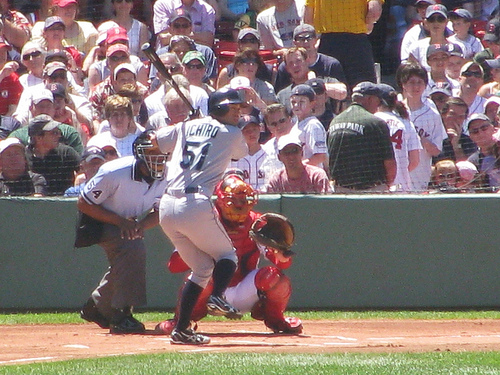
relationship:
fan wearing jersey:
[397, 63, 450, 155] [405, 101, 448, 191]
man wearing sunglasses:
[105, 43, 135, 75] [106, 53, 128, 62]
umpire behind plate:
[72, 125, 172, 337] [153, 329, 173, 345]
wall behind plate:
[2, 193, 500, 318] [153, 329, 173, 345]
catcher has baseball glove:
[152, 172, 303, 336] [247, 212, 296, 259]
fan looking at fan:
[324, 82, 393, 197] [397, 63, 450, 155]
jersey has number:
[154, 111, 249, 194] [176, 138, 213, 174]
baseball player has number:
[149, 85, 249, 346] [176, 138, 213, 174]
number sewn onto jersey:
[176, 138, 213, 174] [154, 111, 249, 194]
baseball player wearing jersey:
[149, 85, 249, 346] [154, 111, 249, 194]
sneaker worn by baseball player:
[169, 326, 212, 346] [149, 85, 249, 346]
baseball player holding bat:
[149, 85, 249, 346] [141, 41, 199, 117]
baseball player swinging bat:
[149, 85, 249, 346] [141, 41, 199, 117]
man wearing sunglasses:
[16, 61, 97, 130] [48, 70, 72, 81]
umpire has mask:
[72, 125, 172, 337] [127, 127, 171, 180]